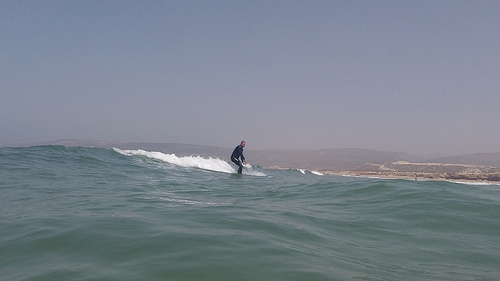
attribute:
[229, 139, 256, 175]
man — surfing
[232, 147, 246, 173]
wetsuit — black, blue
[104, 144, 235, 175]
wave — small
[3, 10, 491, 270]
weather — hazy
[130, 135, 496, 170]
range — here, mountain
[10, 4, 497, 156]
sky — cloudless, clear, grey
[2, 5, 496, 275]
day — calm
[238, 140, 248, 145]
hair — short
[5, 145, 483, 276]
water — wav, green, ocean, blue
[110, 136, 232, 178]
waves — white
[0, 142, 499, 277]
waters — blue, green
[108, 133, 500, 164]
tops — mountains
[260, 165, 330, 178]
splashes — white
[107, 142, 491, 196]
shore — brown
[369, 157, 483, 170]
road — sandy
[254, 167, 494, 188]
strip — beach, long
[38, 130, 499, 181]
landscape — grey, foggy